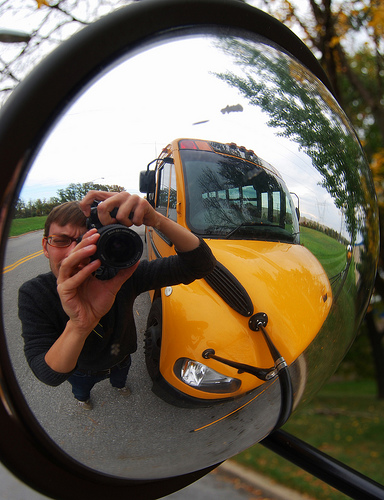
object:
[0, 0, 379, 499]
picture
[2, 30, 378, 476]
reflection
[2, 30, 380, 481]
mirror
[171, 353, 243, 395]
headlight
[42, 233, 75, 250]
glasses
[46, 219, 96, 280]
face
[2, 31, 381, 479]
picture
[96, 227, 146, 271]
lens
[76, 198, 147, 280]
camera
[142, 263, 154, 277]
black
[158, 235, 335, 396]
yellow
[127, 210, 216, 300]
arm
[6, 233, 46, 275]
road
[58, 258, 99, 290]
fingers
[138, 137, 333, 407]
bus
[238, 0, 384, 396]
tree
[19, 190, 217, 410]
man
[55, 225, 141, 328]
hand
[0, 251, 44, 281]
yellow line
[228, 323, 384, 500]
green grass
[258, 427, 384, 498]
black pole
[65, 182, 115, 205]
trees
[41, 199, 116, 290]
head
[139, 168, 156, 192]
view mirror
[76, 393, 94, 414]
shoe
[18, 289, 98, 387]
arm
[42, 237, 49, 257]
ear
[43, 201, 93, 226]
hair